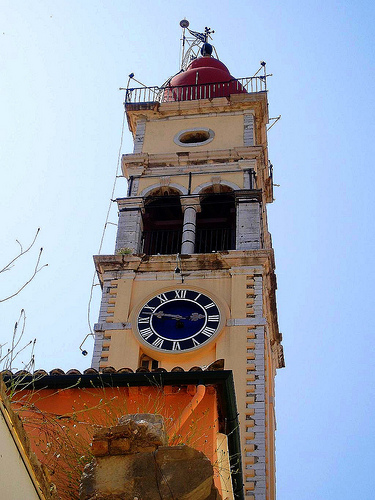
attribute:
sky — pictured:
[4, 7, 369, 445]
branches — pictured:
[3, 310, 32, 402]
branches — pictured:
[0, 355, 42, 405]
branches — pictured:
[20, 371, 89, 405]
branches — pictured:
[11, 390, 119, 430]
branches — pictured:
[20, 423, 118, 458]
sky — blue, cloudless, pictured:
[0, 2, 373, 498]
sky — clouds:
[297, 57, 342, 140]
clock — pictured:
[128, 279, 221, 344]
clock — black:
[128, 274, 236, 349]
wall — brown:
[211, 115, 239, 142]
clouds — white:
[309, 330, 369, 399]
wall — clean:
[114, 267, 157, 307]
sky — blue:
[37, 25, 122, 67]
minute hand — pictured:
[141, 310, 183, 320]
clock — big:
[131, 281, 225, 357]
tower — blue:
[0, 16, 288, 497]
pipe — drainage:
[267, 158, 278, 204]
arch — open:
[134, 180, 189, 260]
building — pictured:
[117, 45, 359, 421]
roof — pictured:
[2, 358, 232, 391]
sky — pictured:
[2, 3, 370, 361]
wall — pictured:
[131, 116, 264, 160]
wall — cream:
[114, 275, 252, 434]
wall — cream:
[146, 123, 246, 151]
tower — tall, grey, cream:
[109, 26, 276, 328]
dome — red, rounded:
[152, 32, 259, 109]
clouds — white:
[24, 28, 104, 128]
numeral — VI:
[166, 335, 184, 352]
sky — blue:
[24, 48, 100, 180]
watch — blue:
[138, 286, 218, 348]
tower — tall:
[84, 16, 283, 498]